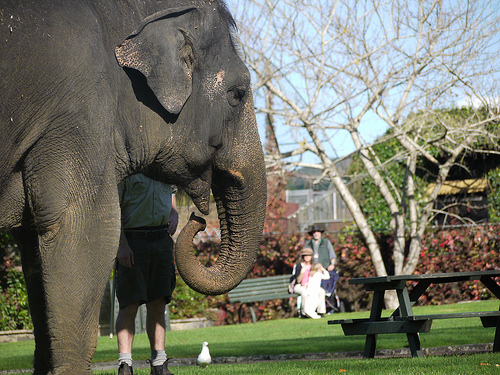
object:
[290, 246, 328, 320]
person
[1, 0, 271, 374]
elephant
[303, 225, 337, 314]
person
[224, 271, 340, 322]
bench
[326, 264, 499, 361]
picnic table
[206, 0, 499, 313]
tree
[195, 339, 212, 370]
bird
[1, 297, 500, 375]
ground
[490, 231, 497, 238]
leaves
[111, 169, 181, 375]
man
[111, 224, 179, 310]
shorts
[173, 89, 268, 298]
trunk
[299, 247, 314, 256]
hat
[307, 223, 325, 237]
hat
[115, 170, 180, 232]
shirt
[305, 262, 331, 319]
child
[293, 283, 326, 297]
lap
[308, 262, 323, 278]
hair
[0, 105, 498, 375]
park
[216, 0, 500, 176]
sky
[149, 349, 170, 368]
socks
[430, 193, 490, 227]
window